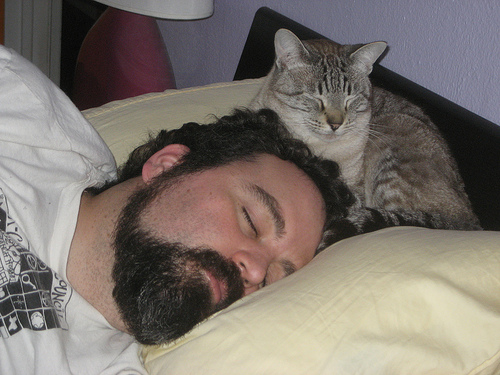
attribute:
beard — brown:
[113, 183, 243, 344]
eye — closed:
[304, 88, 321, 104]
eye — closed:
[345, 95, 357, 106]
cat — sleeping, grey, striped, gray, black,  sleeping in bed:
[244, 28, 483, 228]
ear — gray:
[271, 25, 310, 68]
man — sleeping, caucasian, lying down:
[1, 48, 342, 373]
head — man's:
[97, 105, 349, 348]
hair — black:
[112, 109, 361, 253]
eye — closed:
[304, 93, 323, 105]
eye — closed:
[340, 97, 360, 107]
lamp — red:
[74, 5, 180, 105]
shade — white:
[96, 2, 227, 27]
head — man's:
[110, 95, 360, 355]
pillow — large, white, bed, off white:
[86, 68, 498, 373]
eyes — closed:
[239, 191, 289, 291]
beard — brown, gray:
[99, 165, 249, 360]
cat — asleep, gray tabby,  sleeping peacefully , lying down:
[247, 25, 474, 245]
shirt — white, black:
[0, 41, 164, 371]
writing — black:
[1, 175, 79, 360]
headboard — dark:
[231, 16, 499, 244]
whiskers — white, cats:
[274, 112, 399, 144]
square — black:
[38, 301, 68, 339]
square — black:
[21, 304, 48, 338]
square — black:
[15, 248, 35, 280]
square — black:
[19, 288, 49, 318]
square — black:
[1, 310, 28, 339]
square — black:
[2, 294, 15, 321]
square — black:
[10, 290, 32, 312]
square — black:
[23, 285, 52, 317]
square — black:
[21, 267, 36, 296]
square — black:
[34, 271, 52, 292]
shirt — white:
[7, 44, 119, 373]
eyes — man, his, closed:
[233, 191, 294, 300]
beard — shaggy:
[111, 177, 209, 347]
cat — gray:
[260, 30, 467, 230]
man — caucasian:
[2, 110, 328, 370]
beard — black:
[115, 236, 244, 342]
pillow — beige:
[348, 230, 482, 367]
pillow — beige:
[367, 231, 474, 372]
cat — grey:
[273, 29, 390, 157]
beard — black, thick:
[119, 244, 236, 342]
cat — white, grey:
[269, 30, 389, 131]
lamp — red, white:
[76, 4, 217, 91]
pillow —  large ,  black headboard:
[294, 236, 484, 324]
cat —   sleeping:
[254, 18, 479, 228]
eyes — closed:
[224, 199, 318, 280]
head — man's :
[269, 19, 388, 150]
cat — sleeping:
[257, 16, 480, 255]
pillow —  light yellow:
[314, 240, 481, 369]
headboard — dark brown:
[238, 7, 484, 235]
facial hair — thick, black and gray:
[116, 203, 243, 353]